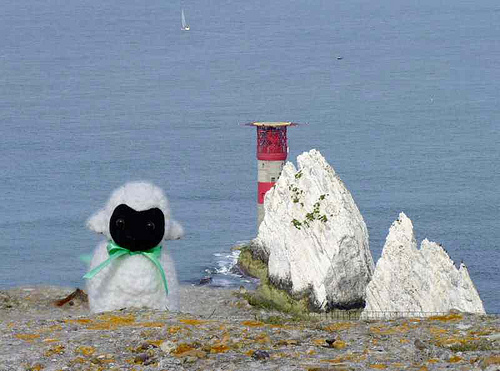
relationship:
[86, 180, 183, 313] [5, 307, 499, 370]
animal on ground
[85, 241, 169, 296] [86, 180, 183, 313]
ribbon on animal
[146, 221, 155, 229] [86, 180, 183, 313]
eye of animal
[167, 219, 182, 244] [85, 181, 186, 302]
ear of animal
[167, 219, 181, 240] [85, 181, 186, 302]
ear of animal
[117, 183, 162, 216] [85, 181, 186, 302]
haed of animal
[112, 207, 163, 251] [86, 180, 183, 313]
face on animal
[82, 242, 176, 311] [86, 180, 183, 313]
body of animal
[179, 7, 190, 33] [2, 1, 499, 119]
boat on water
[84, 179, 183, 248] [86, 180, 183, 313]
haed of animal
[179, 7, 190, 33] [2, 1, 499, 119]
boat in water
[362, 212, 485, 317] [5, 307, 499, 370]
rock on ground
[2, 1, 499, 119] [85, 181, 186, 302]
water behind animal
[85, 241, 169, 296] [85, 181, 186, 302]
ribbon on animal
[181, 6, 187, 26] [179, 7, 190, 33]
sail on boat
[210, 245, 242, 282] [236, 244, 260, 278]
waves hitting rocks